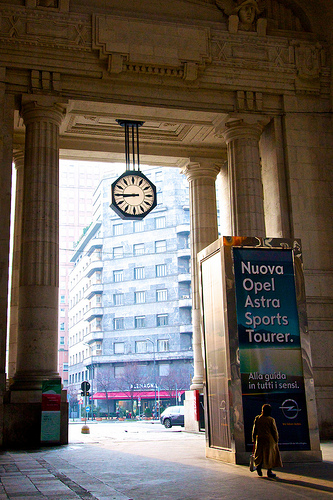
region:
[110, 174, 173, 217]
The clock is white and black.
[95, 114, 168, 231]
The clock is hanging.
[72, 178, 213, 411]
Many windows are on the side of the building.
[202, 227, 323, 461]
The sign is large.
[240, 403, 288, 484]
She is reading the sign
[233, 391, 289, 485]
She is wearing a jacket.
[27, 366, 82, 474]
The sign is white, red and green.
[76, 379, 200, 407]
The awning is red.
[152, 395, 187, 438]
The car is driving.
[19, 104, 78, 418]
The pillars are tan.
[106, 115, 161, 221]
a black clock hanging from the ceiling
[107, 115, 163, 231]
the clock is in the entrance of the building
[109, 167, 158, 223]
there are no numbers on the clock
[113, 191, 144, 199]
the clock has 2 hands on its face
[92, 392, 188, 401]
the awning is pink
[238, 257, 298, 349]
the sign is in spanish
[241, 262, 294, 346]
the writing is in white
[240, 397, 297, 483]
the woman is standing in front of the sign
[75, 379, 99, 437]
a stop sign at the front of the entrance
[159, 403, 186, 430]
the car is parked in front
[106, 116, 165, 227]
back and white clock hanging down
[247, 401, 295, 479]
person in coat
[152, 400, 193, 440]
car on the street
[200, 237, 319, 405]
advertising on a pillar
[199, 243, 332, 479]
person looking at advertising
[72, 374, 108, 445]
street sign near the street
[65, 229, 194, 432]
building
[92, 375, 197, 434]
store across the street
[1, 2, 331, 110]
design on the inside of the building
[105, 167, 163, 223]
clock with no numbers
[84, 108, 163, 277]
the clock is hanging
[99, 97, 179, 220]
the clock is hanging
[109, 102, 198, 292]
the clock is hanging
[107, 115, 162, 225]
an analog clock hanging in the doorway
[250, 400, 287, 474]
a woman wearing a tan coat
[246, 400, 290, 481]
a woman carrying a bag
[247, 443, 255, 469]
a white bag with a red strap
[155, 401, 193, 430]
a black car driving past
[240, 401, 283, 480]
a woman with her hand in her pocket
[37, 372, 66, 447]
a green and red sign on the wall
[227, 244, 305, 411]
a large advertisement on the wall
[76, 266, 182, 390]
a large building with lots of windows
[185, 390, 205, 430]
a red sing on the curb